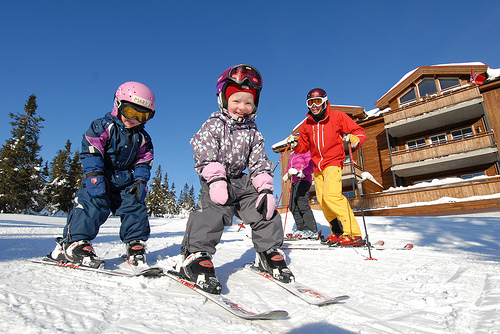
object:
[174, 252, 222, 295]
shoe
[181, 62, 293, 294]
person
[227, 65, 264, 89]
goggles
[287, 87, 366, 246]
child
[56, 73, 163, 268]
child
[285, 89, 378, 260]
skier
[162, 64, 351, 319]
skier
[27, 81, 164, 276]
skier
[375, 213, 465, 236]
ground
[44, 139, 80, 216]
trees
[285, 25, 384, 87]
sky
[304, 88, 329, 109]
helmet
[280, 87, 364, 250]
man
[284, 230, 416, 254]
skis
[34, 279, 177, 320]
ice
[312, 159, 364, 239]
pants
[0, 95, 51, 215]
tree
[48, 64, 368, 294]
people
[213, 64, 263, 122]
purple helmet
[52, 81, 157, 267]
girl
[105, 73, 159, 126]
helmet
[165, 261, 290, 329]
machine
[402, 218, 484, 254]
shadow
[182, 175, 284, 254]
pants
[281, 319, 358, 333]
shadow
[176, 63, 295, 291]
child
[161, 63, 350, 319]
toddler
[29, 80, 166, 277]
toddler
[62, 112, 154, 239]
snowsuit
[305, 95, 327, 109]
spects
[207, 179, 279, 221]
gloves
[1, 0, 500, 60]
sky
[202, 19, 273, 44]
white clouds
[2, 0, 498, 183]
blue sky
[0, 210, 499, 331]
snow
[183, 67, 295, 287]
kid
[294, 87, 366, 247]
person